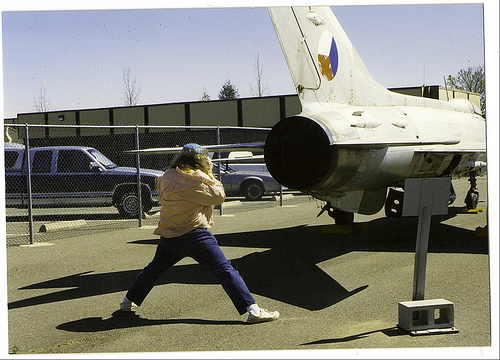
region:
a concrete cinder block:
[381, 293, 456, 338]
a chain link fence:
[26, 116, 159, 257]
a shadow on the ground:
[282, 227, 399, 334]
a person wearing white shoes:
[205, 133, 309, 350]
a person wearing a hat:
[174, 139, 211, 197]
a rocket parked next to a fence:
[273, 88, 471, 261]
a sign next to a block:
[393, 167, 459, 339]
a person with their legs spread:
[111, 140, 242, 328]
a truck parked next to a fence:
[33, 115, 163, 245]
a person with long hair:
[146, 129, 218, 194]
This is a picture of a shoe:
[229, 306, 354, 316]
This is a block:
[359, 259, 479, 336]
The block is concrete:
[362, 287, 495, 342]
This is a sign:
[366, 180, 494, 218]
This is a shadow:
[269, 223, 364, 310]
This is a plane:
[294, 101, 423, 196]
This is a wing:
[195, 34, 413, 82]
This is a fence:
[61, 139, 159, 249]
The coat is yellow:
[157, 207, 169, 227]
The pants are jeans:
[137, 248, 324, 313]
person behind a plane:
[106, 118, 291, 318]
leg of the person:
[197, 235, 298, 336]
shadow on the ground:
[55, 287, 106, 343]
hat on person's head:
[160, 126, 224, 185]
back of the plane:
[229, 90, 409, 229]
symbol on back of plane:
[298, 22, 358, 94]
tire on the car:
[110, 188, 147, 227]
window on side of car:
[51, 141, 93, 191]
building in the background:
[80, 90, 185, 145]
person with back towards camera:
[79, 105, 320, 319]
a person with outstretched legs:
[96, 142, 287, 337]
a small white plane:
[236, 11, 492, 257]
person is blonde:
[133, 130, 242, 250]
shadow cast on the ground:
[239, 208, 394, 304]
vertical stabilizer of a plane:
[276, 11, 394, 93]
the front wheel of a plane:
[457, 171, 484, 218]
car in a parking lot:
[14, 114, 266, 203]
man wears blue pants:
[113, 133, 288, 329]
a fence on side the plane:
[14, 93, 329, 235]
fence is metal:
[6, 105, 153, 234]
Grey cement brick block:
[398, 298, 455, 332]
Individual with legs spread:
[114, 230, 279, 323]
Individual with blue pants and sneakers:
[116, 227, 278, 322]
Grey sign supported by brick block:
[394, 177, 457, 333]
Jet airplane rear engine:
[260, 112, 331, 192]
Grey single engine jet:
[265, 6, 488, 216]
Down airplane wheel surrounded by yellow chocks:
[461, 190, 482, 212]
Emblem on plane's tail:
[312, 44, 342, 80]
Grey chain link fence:
[4, 122, 255, 217]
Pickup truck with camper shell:
[7, 145, 162, 215]